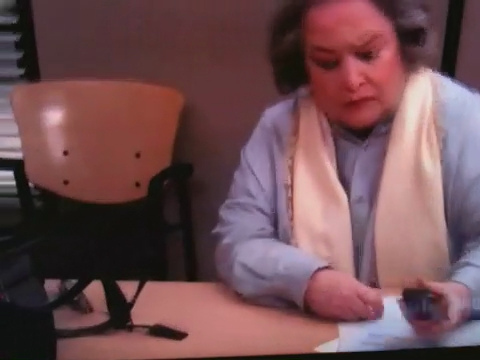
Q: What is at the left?
A: A chair.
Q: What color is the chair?
A: Brown.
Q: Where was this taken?
A: In a room.